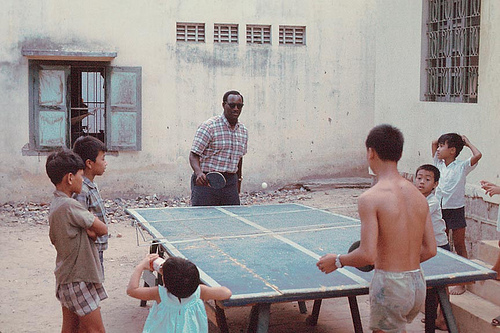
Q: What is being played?
A: Ping pong.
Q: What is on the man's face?
A: Black shades.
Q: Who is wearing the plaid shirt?
A: The man with shades.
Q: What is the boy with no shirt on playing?
A: Ping pong.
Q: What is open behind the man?
A: A window.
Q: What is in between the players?
A: A ping pong table.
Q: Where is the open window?
A: On the building.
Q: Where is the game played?
A: Outside a building.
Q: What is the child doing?
A: Drinking.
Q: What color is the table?
A: Green.